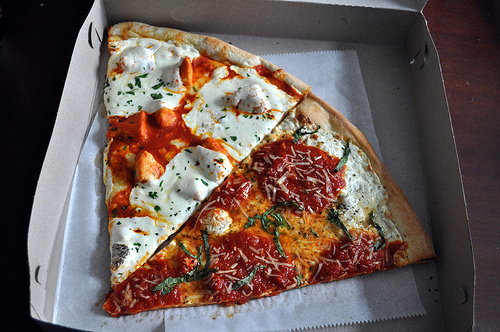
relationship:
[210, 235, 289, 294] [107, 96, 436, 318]
pepperoni on slice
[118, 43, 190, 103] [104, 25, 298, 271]
cheese on slice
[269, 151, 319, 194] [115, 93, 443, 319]
cheese on pizza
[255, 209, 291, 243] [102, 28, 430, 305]
parsley on pizza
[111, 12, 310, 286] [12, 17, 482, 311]
slices inside box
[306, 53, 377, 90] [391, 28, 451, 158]
paper between box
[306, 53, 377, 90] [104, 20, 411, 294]
paper between pizza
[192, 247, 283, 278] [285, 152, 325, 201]
ingredient covered sauce